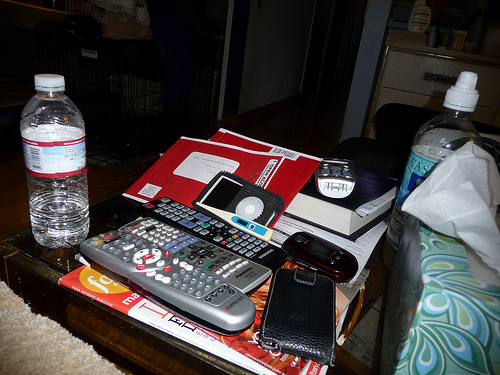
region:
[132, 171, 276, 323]
Three remote controls sitting on the table.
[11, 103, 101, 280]
A bottle of water on the table.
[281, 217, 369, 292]
A cell phone on the table.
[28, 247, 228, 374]
The table is wooden.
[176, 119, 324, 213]
The letters are red.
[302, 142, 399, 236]
A remote control sitting on a book.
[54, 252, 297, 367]
Remote controls sitting on the magazine.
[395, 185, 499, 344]
A box of tissue next to the water bottle.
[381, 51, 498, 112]
A dresser drawer in the corner.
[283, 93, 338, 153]
The flooring is wood.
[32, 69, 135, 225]
the bottle is plastic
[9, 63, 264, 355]
the bottle is plastic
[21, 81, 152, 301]
the bottle is plastic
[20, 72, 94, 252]
plastic of water with red ,white and blue label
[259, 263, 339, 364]
black leather folding wallet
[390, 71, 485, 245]
plastic bottle of water with blue label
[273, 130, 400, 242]
thick black book with paper inside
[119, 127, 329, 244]
2 red photo envelopes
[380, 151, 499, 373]
white tissue in a box with mostly green design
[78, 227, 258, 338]
remote control with round edges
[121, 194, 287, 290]
remote controls with sharp edges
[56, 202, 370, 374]
magazine with orange and white graphics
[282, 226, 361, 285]
small black portable pohone with round edges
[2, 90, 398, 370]
the table is cluttered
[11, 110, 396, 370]
the table is wooden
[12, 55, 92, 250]
the bottle of water on the table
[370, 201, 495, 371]
the box of tissues on the table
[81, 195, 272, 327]
the remotes on the table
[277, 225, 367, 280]
the cellphone on the table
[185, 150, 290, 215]
the ipod on the table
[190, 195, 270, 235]
the thermometer on the table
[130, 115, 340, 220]
the mail on the table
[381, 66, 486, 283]
the bottle of water on the table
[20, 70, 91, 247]
the closed water bottle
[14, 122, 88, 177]
the label on the water bottle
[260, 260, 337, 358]
the leather case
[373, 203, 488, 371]
the blue and green tissue box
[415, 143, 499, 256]
the tissue sticking out of the box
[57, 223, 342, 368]
the magazine under the remotes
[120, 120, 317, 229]
the netflix envelopes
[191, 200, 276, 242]
the thermometer near the remotes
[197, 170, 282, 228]
the ipod on the netflix envelopes